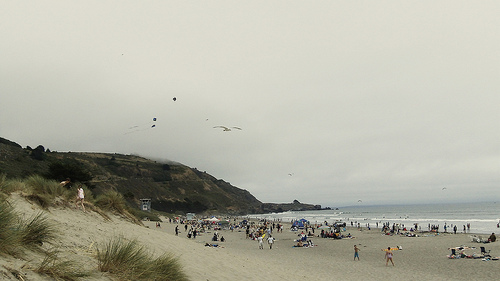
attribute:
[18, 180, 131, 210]
grass — small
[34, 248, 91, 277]
grass — small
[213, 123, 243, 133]
seabird — large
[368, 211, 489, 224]
wave — small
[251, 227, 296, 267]
shirt — white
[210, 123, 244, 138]
seagull — lone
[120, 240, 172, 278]
grass — small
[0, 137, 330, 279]
hill — large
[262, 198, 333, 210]
rock — large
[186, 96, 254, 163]
seagull — large, flying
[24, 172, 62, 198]
grass — small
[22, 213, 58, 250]
grass — small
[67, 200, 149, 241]
hill — sandy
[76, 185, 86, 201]
shirt — white